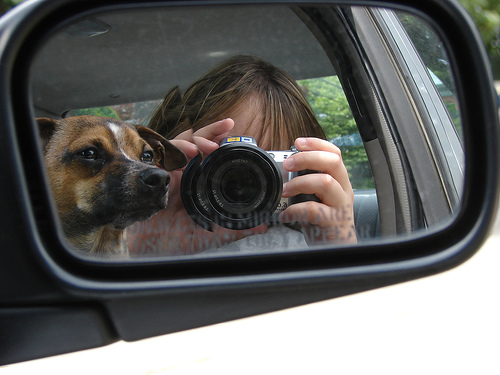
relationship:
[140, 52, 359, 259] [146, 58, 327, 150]
girl has hair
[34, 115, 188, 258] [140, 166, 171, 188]
dog has nose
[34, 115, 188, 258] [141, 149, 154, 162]
dog has eye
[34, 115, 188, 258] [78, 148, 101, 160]
dog has eye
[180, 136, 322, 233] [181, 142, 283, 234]
camera has lens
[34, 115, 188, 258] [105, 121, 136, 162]
dog has streak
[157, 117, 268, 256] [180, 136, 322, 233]
hand holding camera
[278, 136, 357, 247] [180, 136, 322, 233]
hand holding camera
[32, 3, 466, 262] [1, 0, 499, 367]
reflection in mirror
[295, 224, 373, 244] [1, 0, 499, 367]
word on mirror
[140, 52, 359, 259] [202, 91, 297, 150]
girl has forehead